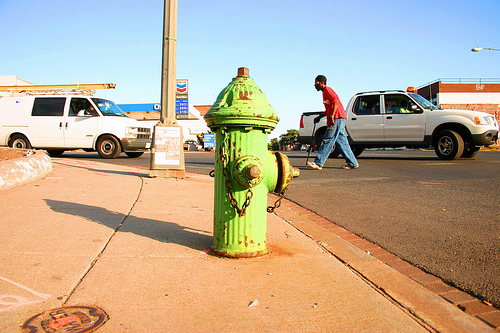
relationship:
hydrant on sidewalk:
[202, 65, 299, 258] [0, 159, 499, 331]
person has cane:
[308, 72, 362, 170] [303, 118, 319, 168]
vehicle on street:
[294, 88, 498, 161] [49, 152, 499, 312]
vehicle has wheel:
[294, 88, 498, 161] [436, 128, 463, 158]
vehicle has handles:
[294, 88, 498, 161] [385, 115, 397, 120]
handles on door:
[385, 115, 397, 120] [383, 94, 427, 142]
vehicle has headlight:
[294, 88, 498, 161] [474, 114, 493, 124]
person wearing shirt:
[308, 72, 362, 170] [319, 84, 347, 120]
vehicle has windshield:
[294, 88, 498, 161] [408, 90, 439, 108]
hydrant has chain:
[202, 65, 299, 258] [220, 162, 253, 218]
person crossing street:
[308, 72, 362, 170] [49, 152, 499, 312]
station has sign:
[100, 104, 216, 151] [175, 76, 188, 117]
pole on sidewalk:
[149, 1, 185, 172] [0, 159, 499, 331]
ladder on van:
[1, 82, 117, 93] [0, 81, 151, 158]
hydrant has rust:
[202, 65, 299, 258] [202, 79, 299, 260]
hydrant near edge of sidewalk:
[202, 65, 299, 258] [0, 159, 499, 331]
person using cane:
[308, 72, 362, 170] [303, 118, 319, 168]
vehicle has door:
[294, 88, 498, 161] [383, 94, 427, 142]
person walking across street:
[308, 72, 362, 170] [49, 152, 499, 312]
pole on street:
[149, 1, 185, 172] [49, 152, 499, 312]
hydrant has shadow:
[202, 65, 299, 258] [40, 194, 213, 252]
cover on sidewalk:
[18, 300, 112, 332] [0, 159, 499, 331]